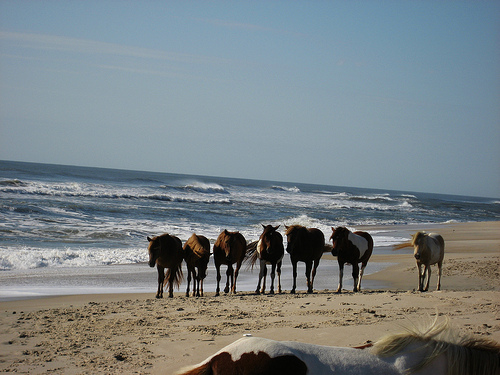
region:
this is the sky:
[49, 2, 117, 24]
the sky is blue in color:
[11, 5, 72, 22]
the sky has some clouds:
[12, 35, 368, 156]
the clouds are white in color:
[13, 42, 163, 100]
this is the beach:
[11, 252, 133, 356]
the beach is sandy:
[35, 315, 150, 360]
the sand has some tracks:
[30, 305, 165, 371]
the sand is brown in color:
[45, 313, 146, 360]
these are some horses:
[133, 226, 443, 281]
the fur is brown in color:
[187, 240, 199, 253]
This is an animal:
[407, 221, 449, 292]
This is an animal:
[325, 216, 371, 291]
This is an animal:
[282, 217, 322, 297]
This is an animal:
[250, 211, 285, 291]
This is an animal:
[210, 210, 245, 300]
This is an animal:
[180, 225, 210, 296]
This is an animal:
[136, 230, 181, 302]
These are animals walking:
[400, 221, 455, 296]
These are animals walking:
[320, 218, 387, 291]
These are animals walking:
[286, 213, 328, 297]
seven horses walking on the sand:
[146, 227, 443, 272]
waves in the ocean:
[189, 154, 225, 211]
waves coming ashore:
[25, 241, 35, 289]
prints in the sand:
[42, 296, 100, 355]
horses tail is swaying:
[399, 227, 441, 264]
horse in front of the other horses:
[324, 328, 453, 374]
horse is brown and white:
[273, 329, 353, 370]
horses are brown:
[152, 226, 250, 258]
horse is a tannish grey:
[409, 244, 445, 275]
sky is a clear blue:
[338, 18, 458, 107]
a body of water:
[1, 157, 496, 266]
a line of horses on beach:
[146, 226, 447, 294]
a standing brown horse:
[146, 231, 182, 298]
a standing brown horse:
[181, 232, 211, 297]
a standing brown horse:
[211, 226, 244, 292]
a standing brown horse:
[249, 222, 286, 297]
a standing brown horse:
[282, 220, 324, 295]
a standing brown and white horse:
[326, 220, 373, 294]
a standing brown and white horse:
[408, 230, 447, 292]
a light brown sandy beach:
[0, 217, 495, 374]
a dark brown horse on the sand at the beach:
[145, 229, 181, 298]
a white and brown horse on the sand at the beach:
[325, 223, 372, 293]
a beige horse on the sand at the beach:
[407, 232, 447, 292]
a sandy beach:
[0, 223, 497, 371]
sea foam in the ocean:
[0, 209, 322, 264]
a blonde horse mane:
[383, 317, 498, 361]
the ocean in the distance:
[1, 154, 498, 266]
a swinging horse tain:
[243, 238, 260, 270]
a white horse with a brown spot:
[171, 333, 498, 373]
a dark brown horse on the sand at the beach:
[282, 224, 327, 300]